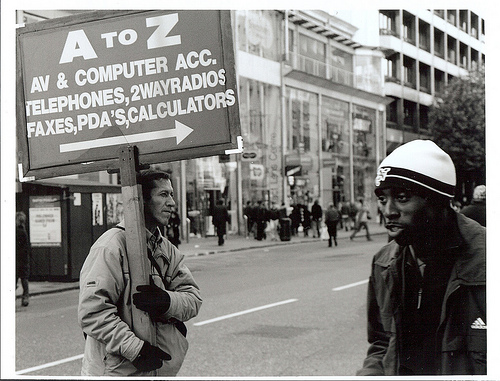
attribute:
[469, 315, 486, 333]
logo — white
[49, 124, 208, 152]
arrow — white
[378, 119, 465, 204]
hat — knit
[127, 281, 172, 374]
gloves — black, worn, heavy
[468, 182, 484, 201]
hair — white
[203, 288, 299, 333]
line — white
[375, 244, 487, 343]
jacket — addidas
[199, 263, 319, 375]
road — paved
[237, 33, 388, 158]
fronts — glass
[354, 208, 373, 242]
person — walking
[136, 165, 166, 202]
hair — short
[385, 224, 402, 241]
mouth — open